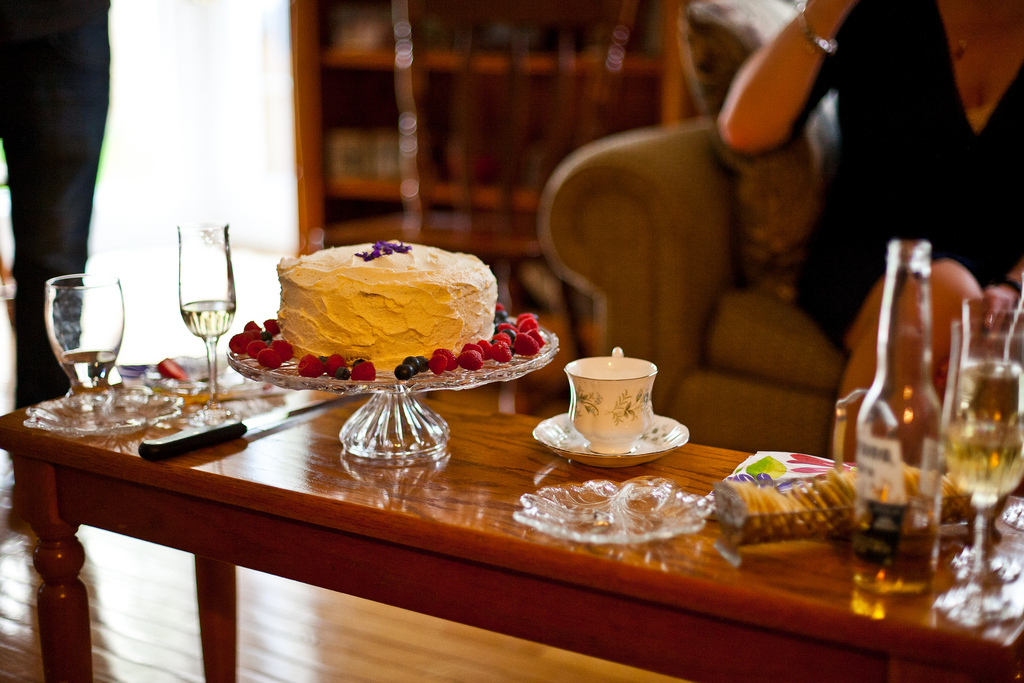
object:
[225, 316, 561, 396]
berries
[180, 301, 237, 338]
wine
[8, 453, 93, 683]
foot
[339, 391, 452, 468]
base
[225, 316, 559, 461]
cake plate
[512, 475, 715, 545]
ashtray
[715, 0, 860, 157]
arm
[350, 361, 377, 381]
raspberry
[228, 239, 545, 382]
cake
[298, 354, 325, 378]
raspberry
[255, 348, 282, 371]
raspberry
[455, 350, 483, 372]
raspberry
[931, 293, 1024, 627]
champagne flute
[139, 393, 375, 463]
knife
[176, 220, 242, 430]
champegne flue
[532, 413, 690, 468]
tea saucer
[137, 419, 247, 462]
handle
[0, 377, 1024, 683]
coffee table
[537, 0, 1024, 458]
sofa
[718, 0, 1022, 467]
person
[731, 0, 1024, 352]
dress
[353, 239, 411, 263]
blueberries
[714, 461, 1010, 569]
crackers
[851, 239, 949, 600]
beer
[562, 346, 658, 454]
cup